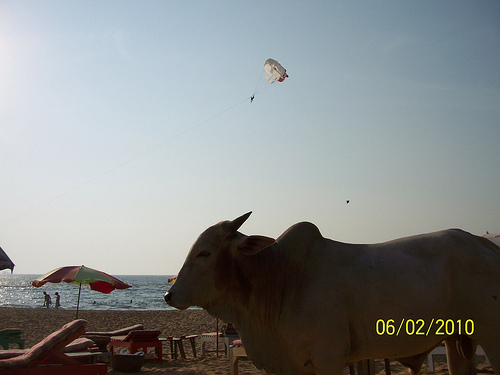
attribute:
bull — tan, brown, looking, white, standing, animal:
[174, 228, 494, 369]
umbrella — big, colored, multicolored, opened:
[51, 264, 116, 316]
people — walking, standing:
[55, 295, 67, 312]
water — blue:
[139, 287, 154, 300]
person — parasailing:
[241, 93, 258, 107]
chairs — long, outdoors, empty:
[103, 327, 157, 356]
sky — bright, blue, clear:
[94, 7, 138, 32]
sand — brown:
[125, 316, 151, 324]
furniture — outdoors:
[123, 325, 201, 355]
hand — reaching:
[41, 298, 46, 302]